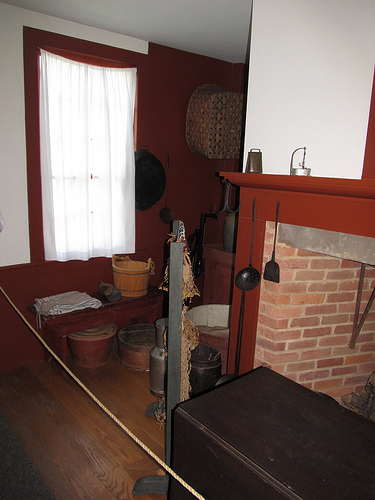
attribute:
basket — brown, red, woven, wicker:
[112, 260, 157, 298]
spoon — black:
[234, 255, 250, 373]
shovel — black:
[256, 189, 295, 292]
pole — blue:
[175, 230, 202, 285]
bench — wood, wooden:
[66, 303, 156, 322]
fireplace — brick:
[247, 250, 362, 400]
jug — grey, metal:
[146, 351, 166, 397]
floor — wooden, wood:
[1, 389, 150, 433]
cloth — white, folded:
[73, 223, 144, 257]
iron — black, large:
[259, 206, 291, 228]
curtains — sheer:
[33, 43, 143, 261]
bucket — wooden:
[110, 283, 145, 298]